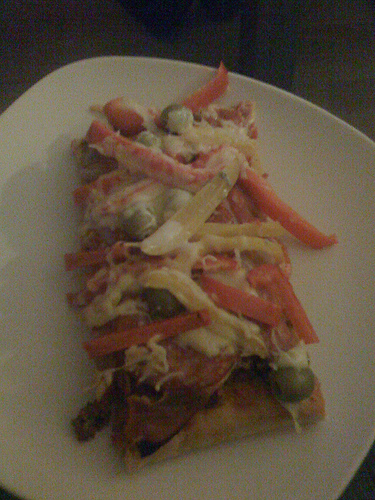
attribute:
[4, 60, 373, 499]
plate — white, square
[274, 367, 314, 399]
pea — green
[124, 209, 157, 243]
pea — green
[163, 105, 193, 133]
pea — green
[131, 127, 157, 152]
pea — green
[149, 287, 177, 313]
pea — green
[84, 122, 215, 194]
pepper — bell, red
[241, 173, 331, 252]
pepper — bell, red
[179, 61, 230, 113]
pepper — bell, red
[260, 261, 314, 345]
pepper — bell, red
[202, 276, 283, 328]
pepper — bell, red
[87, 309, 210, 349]
pepper — bell, red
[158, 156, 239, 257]
pepper — bell, yellow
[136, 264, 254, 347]
pepper — bell, yellow